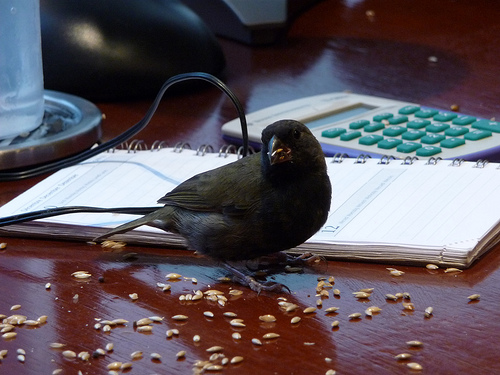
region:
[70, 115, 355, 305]
A bird standing on a desk.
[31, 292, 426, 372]
Bird seed on the desk.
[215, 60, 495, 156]
A calculator on the desk.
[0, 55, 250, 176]
The electrical cord is black.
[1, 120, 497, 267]
The spiral notebook next to the bird.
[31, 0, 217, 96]
A black object in the background.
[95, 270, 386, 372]
A shadow on the bird on the desk.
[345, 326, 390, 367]
The table is made out of wood.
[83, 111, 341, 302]
The bird is black.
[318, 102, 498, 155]
Blue buttons on the calculator.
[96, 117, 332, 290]
a black bird on a wooden table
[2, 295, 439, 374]
sunflower seeds spread on a wooden table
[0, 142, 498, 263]
an opened white notebook on a table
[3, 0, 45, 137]
a glass of water on an ashtray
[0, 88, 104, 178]
a silver ashtray on a wooden table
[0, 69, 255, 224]
a black wire on a wooden table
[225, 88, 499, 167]
a calculator on a wooden table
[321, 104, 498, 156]
green button of a calculator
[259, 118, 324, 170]
bird with a sunflower seed in its mouth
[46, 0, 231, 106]
a black computer mouse on a table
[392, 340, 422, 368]
Three peices of birdseed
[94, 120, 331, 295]
A small black bird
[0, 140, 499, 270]
A spiral ring notebook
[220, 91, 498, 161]
A purple, green and gray calculator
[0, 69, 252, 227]
Part of a black wire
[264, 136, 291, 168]
A bird's beak full of food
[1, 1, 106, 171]
Part of an empty bird feeder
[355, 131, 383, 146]
A green calculator button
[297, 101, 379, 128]
A calculator's screen that is off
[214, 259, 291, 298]
A bird's right foot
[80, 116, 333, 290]
a small bird on a desk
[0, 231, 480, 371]
seeds on a desk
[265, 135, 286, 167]
the beak of a black bird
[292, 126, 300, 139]
the eye of a bird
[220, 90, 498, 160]
a calculator on a desk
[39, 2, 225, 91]
a foam piece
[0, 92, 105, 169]
a small metal coaster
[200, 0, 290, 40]
a plastic base of a phone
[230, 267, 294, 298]
the claw of a bird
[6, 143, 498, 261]
a white note pad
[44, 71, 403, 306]
bird on a desk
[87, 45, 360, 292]
bird on a brown desk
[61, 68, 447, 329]
a dark bird on a desk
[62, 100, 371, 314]
a dark bird on a brown desk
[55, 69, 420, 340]
a bird that is inside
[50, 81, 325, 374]
a small bird that is inside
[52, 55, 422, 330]
a small bird on a desk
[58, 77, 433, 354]
a small bird on a brown desk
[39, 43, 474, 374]
a bird inside on a desk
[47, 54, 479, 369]
a small bird inside on a desk